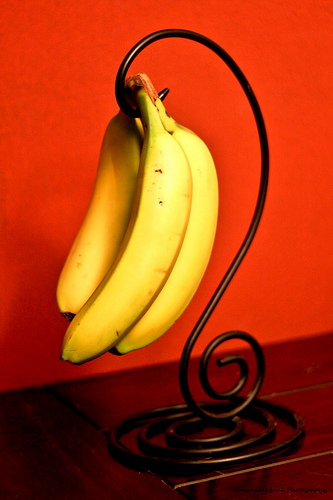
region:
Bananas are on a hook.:
[38, 24, 314, 485]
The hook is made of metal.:
[103, 27, 298, 478]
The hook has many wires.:
[97, 24, 308, 477]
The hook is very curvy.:
[99, 22, 304, 475]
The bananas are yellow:
[52, 71, 227, 364]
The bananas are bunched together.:
[41, 71, 226, 369]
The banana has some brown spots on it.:
[148, 162, 172, 210]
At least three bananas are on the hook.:
[49, 68, 223, 366]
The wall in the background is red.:
[1, 0, 331, 392]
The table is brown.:
[0, 328, 332, 498]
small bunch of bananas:
[43, 48, 199, 337]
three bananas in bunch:
[92, 102, 179, 321]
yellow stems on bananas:
[124, 76, 155, 142]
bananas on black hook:
[108, 66, 173, 158]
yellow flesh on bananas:
[52, 120, 218, 299]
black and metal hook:
[90, 65, 257, 406]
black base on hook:
[121, 388, 264, 484]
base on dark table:
[57, 389, 268, 496]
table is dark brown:
[263, 340, 307, 404]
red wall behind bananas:
[281, 156, 331, 301]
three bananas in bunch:
[68, 95, 234, 362]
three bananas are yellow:
[30, 102, 220, 376]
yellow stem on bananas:
[111, 84, 196, 152]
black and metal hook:
[108, 62, 158, 143]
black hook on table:
[51, 56, 288, 489]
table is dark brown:
[89, 342, 331, 498]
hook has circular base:
[124, 385, 300, 481]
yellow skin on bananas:
[73, 96, 194, 347]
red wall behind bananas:
[280, 56, 331, 178]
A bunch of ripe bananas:
[53, 84, 218, 366]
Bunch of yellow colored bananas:
[56, 108, 219, 365]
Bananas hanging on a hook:
[57, 112, 222, 363]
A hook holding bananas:
[114, 23, 278, 415]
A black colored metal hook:
[116, 23, 287, 419]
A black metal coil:
[109, 397, 306, 471]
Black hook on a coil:
[107, 30, 303, 477]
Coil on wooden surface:
[108, 395, 302, 470]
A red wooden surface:
[0, 328, 332, 497]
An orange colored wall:
[0, 1, 332, 390]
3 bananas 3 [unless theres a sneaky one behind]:
[47, 69, 226, 371]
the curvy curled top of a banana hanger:
[105, 20, 263, 121]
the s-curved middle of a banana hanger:
[192, 20, 280, 324]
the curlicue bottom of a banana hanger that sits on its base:
[176, 316, 270, 423]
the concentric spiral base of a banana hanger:
[92, 385, 316, 480]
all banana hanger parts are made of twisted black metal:
[95, 19, 313, 479]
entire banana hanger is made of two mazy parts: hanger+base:
[94, 18, 328, 482]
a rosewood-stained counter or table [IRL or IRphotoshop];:
[0, 321, 332, 498]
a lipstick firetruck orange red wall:
[0, 0, 331, 393]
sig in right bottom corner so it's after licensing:
[215, 475, 332, 499]